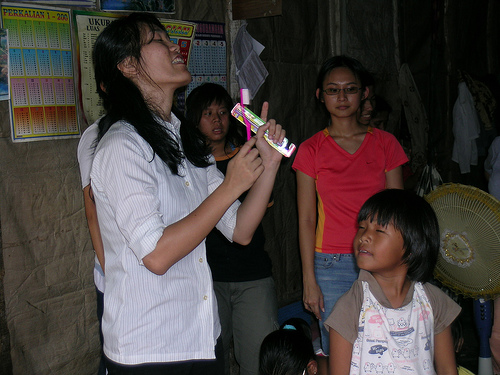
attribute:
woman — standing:
[292, 56, 410, 355]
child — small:
[323, 188, 464, 374]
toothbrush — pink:
[240, 88, 252, 141]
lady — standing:
[90, 12, 286, 373]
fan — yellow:
[424, 182, 499, 372]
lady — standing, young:
[184, 82, 281, 374]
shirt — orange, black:
[206, 147, 276, 283]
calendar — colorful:
[1, 2, 83, 144]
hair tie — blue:
[284, 323, 296, 329]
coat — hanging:
[398, 60, 432, 163]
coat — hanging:
[450, 80, 482, 173]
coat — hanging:
[466, 74, 499, 157]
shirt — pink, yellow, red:
[291, 126, 409, 255]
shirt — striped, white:
[88, 112, 242, 366]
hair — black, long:
[88, 13, 214, 176]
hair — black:
[184, 83, 248, 153]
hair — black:
[357, 188, 440, 283]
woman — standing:
[77, 113, 105, 348]